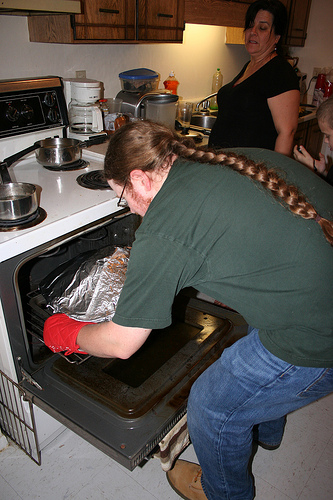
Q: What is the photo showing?
A: It is showing a kitchen.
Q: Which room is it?
A: It is a kitchen.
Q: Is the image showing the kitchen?
A: Yes, it is showing the kitchen.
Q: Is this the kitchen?
A: Yes, it is the kitchen.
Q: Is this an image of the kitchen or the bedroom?
A: It is showing the kitchen.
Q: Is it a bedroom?
A: No, it is a kitchen.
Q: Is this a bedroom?
A: No, it is a kitchen.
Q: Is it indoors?
A: Yes, it is indoors.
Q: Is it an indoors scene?
A: Yes, it is indoors.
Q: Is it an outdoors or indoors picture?
A: It is indoors.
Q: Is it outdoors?
A: No, it is indoors.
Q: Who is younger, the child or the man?
A: The child is younger than the man.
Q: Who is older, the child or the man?
A: The man is older than the child.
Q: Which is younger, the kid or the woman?
A: The kid is younger than the woman.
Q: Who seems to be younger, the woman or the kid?
A: The kid is younger than the woman.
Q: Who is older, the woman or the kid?
A: The woman is older than the kid.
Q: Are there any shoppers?
A: No, there are no shoppers.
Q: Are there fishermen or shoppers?
A: No, there are no shoppers or fishermen.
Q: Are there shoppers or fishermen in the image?
A: No, there are no shoppers or fishermen.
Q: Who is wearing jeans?
A: The man is wearing jeans.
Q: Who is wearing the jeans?
A: The man is wearing jeans.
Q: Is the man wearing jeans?
A: Yes, the man is wearing jeans.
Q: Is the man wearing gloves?
A: No, the man is wearing jeans.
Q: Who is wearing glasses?
A: The man is wearing glasses.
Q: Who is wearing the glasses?
A: The man is wearing glasses.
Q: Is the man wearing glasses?
A: Yes, the man is wearing glasses.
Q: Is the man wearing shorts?
A: No, the man is wearing glasses.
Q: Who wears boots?
A: The man wears boots.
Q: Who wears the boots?
A: The man wears boots.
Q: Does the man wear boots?
A: Yes, the man wears boots.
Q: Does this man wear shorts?
A: No, the man wears boots.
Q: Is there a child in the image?
A: Yes, there is a child.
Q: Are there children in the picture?
A: Yes, there is a child.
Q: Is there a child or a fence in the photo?
A: Yes, there is a child.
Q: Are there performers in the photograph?
A: No, there are no performers.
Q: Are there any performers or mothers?
A: No, there are no performers or mothers.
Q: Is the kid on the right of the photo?
A: Yes, the kid is on the right of the image.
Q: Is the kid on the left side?
A: No, the kid is on the right of the image.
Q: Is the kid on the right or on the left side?
A: The kid is on the right of the image.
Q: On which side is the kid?
A: The kid is on the right of the image.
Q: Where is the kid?
A: The kid is in the kitchen.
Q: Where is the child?
A: The kid is in the kitchen.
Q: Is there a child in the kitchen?
A: Yes, there is a child in the kitchen.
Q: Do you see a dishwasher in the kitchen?
A: No, there is a child in the kitchen.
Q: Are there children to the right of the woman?
A: Yes, there is a child to the right of the woman.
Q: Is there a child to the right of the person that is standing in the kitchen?
A: Yes, there is a child to the right of the woman.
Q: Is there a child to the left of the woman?
A: No, the child is to the right of the woman.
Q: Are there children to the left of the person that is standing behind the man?
A: No, the child is to the right of the woman.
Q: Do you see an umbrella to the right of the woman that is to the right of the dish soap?
A: No, there is a child to the right of the woman.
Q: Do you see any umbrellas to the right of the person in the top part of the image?
A: No, there is a child to the right of the woman.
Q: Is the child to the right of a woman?
A: Yes, the child is to the right of a woman.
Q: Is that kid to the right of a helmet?
A: No, the kid is to the right of a woman.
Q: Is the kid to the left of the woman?
A: No, the kid is to the right of the woman.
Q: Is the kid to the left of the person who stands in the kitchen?
A: No, the kid is to the right of the woman.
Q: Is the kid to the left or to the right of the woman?
A: The kid is to the right of the woman.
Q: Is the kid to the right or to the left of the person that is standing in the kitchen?
A: The kid is to the right of the woman.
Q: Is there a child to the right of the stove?
A: Yes, there is a child to the right of the stove.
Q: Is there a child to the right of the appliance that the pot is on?
A: Yes, there is a child to the right of the stove.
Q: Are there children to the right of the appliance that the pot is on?
A: Yes, there is a child to the right of the stove.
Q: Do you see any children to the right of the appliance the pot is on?
A: Yes, there is a child to the right of the stove.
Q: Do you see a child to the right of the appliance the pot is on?
A: Yes, there is a child to the right of the stove.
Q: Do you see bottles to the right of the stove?
A: No, there is a child to the right of the stove.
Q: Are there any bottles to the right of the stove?
A: No, there is a child to the right of the stove.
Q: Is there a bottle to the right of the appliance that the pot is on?
A: No, there is a child to the right of the stove.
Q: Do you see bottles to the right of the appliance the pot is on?
A: No, there is a child to the right of the stove.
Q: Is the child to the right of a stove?
A: Yes, the child is to the right of a stove.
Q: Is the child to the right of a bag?
A: No, the child is to the right of a stove.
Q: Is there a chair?
A: No, there are no chairs.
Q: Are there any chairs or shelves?
A: No, there are no chairs or shelves.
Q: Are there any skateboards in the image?
A: No, there are no skateboards.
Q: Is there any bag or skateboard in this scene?
A: No, there are no skateboards or bags.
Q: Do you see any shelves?
A: No, there are no shelves.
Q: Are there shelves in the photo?
A: No, there are no shelves.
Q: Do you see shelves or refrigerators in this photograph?
A: No, there are no shelves or refrigerators.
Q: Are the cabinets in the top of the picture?
A: Yes, the cabinets are in the top of the image.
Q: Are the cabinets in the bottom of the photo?
A: No, the cabinets are in the top of the image.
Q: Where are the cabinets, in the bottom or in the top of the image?
A: The cabinets are in the top of the image.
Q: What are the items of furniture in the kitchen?
A: The pieces of furniture are cabinets.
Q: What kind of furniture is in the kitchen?
A: The pieces of furniture are cabinets.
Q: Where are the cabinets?
A: The cabinets are in the kitchen.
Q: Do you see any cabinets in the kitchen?
A: Yes, there are cabinets in the kitchen.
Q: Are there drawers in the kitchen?
A: No, there are cabinets in the kitchen.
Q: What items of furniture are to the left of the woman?
A: The pieces of furniture are cabinets.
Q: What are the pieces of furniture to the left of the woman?
A: The pieces of furniture are cabinets.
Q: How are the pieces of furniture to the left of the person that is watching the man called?
A: The pieces of furniture are cabinets.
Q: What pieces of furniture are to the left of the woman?
A: The pieces of furniture are cabinets.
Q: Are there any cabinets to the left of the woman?
A: Yes, there are cabinets to the left of the woman.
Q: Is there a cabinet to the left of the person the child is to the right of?
A: Yes, there are cabinets to the left of the woman.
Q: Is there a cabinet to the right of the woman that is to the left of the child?
A: No, the cabinets are to the left of the woman.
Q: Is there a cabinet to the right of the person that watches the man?
A: No, the cabinets are to the left of the woman.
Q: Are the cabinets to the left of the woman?
A: Yes, the cabinets are to the left of the woman.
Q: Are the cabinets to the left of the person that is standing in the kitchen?
A: Yes, the cabinets are to the left of the woman.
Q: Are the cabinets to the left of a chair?
A: No, the cabinets are to the left of the woman.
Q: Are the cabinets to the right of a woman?
A: No, the cabinets are to the left of a woman.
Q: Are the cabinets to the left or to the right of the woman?
A: The cabinets are to the left of the woman.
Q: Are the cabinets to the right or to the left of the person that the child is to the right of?
A: The cabinets are to the left of the woman.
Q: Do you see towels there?
A: Yes, there is a towel.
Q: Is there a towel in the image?
A: Yes, there is a towel.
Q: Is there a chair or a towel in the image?
A: Yes, there is a towel.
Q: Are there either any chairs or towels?
A: Yes, there is a towel.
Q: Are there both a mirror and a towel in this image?
A: No, there is a towel but no mirrors.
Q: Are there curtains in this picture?
A: No, there are no curtains.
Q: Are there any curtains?
A: No, there are no curtains.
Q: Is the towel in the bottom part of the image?
A: Yes, the towel is in the bottom of the image.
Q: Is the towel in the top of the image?
A: No, the towel is in the bottom of the image.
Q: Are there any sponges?
A: No, there are no sponges.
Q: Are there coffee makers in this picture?
A: Yes, there is a coffee maker.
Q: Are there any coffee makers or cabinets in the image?
A: Yes, there is a coffee maker.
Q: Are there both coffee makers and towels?
A: Yes, there are both a coffee maker and a towel.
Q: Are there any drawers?
A: No, there are no drawers.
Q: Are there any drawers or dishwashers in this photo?
A: No, there are no drawers or dishwashers.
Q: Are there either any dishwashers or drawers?
A: No, there are no drawers or dishwashers.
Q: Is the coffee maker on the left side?
A: Yes, the coffee maker is on the left of the image.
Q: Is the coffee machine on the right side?
A: No, the coffee machine is on the left of the image.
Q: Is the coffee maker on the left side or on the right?
A: The coffee maker is on the left of the image.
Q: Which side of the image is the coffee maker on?
A: The coffee maker is on the left of the image.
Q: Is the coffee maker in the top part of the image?
A: Yes, the coffee maker is in the top of the image.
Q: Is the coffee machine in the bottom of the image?
A: No, the coffee machine is in the top of the image.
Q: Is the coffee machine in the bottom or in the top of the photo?
A: The coffee machine is in the top of the image.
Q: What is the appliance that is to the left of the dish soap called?
A: The appliance is a coffee maker.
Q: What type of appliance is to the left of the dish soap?
A: The appliance is a coffee maker.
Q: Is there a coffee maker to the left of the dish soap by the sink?
A: Yes, there is a coffee maker to the left of the dish soap.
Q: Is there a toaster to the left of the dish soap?
A: No, there is a coffee maker to the left of the dish soap.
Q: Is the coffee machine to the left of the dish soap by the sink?
A: Yes, the coffee machine is to the left of the dish soap.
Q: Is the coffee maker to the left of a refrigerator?
A: No, the coffee maker is to the left of the dish soap.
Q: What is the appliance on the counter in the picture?
A: The appliance is a coffee maker.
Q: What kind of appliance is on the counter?
A: The appliance is a coffee maker.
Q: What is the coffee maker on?
A: The coffee maker is on the counter.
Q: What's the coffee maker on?
A: The coffee maker is on the counter.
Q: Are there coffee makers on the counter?
A: Yes, there is a coffee maker on the counter.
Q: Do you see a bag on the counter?
A: No, there is a coffee maker on the counter.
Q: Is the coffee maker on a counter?
A: Yes, the coffee maker is on a counter.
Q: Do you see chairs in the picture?
A: No, there are no chairs.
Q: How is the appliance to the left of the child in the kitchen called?
A: The appliance is a stove.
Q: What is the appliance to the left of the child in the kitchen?
A: The appliance is a stove.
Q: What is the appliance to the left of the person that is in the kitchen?
A: The appliance is a stove.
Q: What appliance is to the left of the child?
A: The appliance is a stove.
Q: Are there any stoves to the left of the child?
A: Yes, there is a stove to the left of the child.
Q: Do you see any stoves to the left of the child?
A: Yes, there is a stove to the left of the child.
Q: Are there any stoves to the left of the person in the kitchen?
A: Yes, there is a stove to the left of the child.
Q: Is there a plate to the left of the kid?
A: No, there is a stove to the left of the kid.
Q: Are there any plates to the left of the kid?
A: No, there is a stove to the left of the kid.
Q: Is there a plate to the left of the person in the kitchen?
A: No, there is a stove to the left of the kid.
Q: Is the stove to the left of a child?
A: Yes, the stove is to the left of a child.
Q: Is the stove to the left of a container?
A: No, the stove is to the left of a child.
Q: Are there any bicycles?
A: No, there are no bicycles.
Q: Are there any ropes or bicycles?
A: No, there are no bicycles or ropes.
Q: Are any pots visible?
A: Yes, there is a pot.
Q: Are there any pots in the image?
A: Yes, there is a pot.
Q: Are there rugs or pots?
A: Yes, there is a pot.